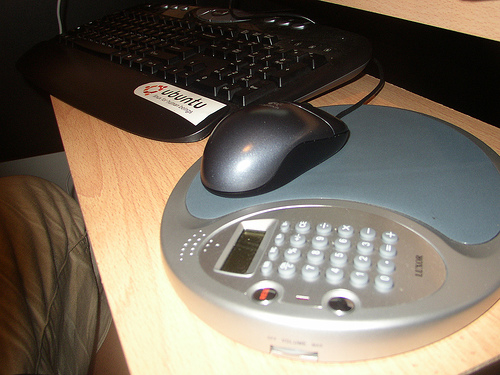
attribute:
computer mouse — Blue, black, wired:
[207, 100, 353, 191]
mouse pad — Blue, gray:
[207, 100, 484, 228]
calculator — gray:
[208, 200, 437, 310]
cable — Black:
[326, 54, 399, 124]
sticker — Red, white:
[132, 72, 221, 128]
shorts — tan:
[4, 169, 106, 369]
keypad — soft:
[277, 217, 405, 291]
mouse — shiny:
[203, 100, 348, 192]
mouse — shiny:
[198, 83, 346, 193]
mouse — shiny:
[190, 94, 356, 188]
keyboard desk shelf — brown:
[67, 80, 497, 369]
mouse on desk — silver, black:
[204, 89, 395, 183]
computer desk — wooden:
[57, 70, 496, 369]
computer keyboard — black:
[18, 16, 373, 148]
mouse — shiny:
[204, 110, 297, 192]